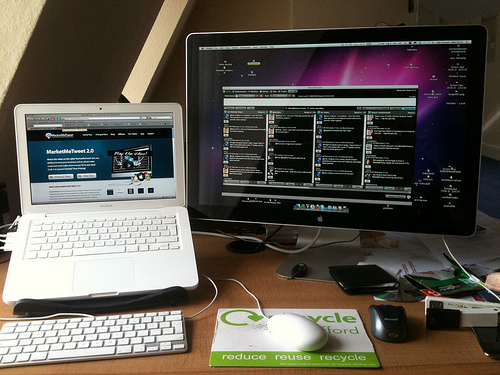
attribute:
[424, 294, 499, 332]
stapler — white, black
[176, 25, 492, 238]
monitor — black framed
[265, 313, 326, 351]
mouse — white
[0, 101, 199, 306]
macbook — white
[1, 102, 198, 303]
laptop — white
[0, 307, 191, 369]
keyboard — white, grey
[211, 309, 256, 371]
mouse pad — white, green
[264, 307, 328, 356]
mouse — white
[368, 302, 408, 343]
mouse — dark grey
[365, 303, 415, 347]
computer mouse — black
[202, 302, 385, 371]
mousepad — green, white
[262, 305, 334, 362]
mouse — white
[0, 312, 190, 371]
keyboard — white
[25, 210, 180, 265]
keyboard — white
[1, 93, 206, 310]
laptop — open, white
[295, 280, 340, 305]
clock — brown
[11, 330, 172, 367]
keyboard — silver, white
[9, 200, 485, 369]
desk — wooden